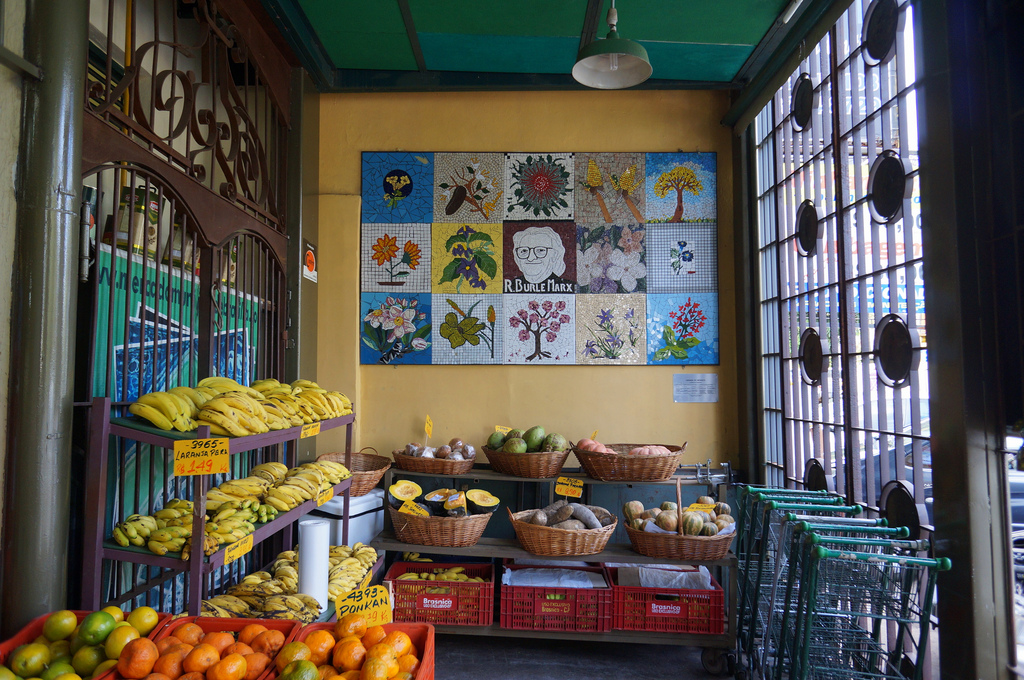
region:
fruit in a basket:
[620, 479, 732, 563]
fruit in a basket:
[514, 490, 623, 574]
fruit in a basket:
[389, 468, 503, 557]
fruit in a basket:
[471, 418, 585, 476]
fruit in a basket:
[394, 397, 483, 464]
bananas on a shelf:
[133, 375, 238, 440]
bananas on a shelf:
[264, 450, 329, 492]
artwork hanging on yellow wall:
[319, 89, 741, 466]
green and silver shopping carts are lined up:
[720, 480, 956, 677]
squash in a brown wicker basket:
[622, 473, 739, 563]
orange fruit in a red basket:
[266, 613, 440, 677]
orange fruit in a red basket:
[107, 610, 305, 677]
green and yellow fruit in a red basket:
[2, 600, 171, 677]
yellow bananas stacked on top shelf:
[113, 367, 367, 457]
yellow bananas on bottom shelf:
[177, 534, 390, 627]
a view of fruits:
[98, 574, 299, 673]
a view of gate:
[825, 195, 965, 467]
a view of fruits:
[128, 313, 341, 444]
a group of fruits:
[163, 395, 353, 652]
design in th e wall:
[496, 160, 601, 339]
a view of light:
[558, 42, 685, 123]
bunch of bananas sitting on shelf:
[137, 382, 198, 441]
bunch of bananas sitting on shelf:
[270, 484, 308, 519]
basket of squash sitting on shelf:
[388, 484, 496, 542]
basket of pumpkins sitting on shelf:
[576, 437, 688, 479]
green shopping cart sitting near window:
[794, 547, 951, 666]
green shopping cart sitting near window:
[744, 496, 863, 662]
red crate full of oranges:
[273, 606, 433, 671]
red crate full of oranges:
[126, 613, 292, 674]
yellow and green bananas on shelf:
[146, 373, 251, 440]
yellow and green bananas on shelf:
[263, 379, 330, 411]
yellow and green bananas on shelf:
[263, 461, 327, 493]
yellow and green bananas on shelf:
[193, 470, 295, 505]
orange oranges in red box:
[169, 625, 209, 648]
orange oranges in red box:
[257, 604, 303, 656]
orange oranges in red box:
[362, 636, 388, 671]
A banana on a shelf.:
[130, 403, 172, 427]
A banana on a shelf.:
[154, 381, 186, 416]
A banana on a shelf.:
[111, 520, 130, 540]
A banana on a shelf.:
[133, 517, 153, 537]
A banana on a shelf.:
[149, 535, 168, 552]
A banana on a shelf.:
[148, 528, 171, 538]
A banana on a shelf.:
[265, 485, 295, 502]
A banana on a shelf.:
[205, 375, 247, 394]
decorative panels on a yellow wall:
[308, 86, 727, 459]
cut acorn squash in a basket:
[385, 467, 499, 548]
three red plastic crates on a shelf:
[385, 549, 741, 649]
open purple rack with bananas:
[77, 374, 390, 625]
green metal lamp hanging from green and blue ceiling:
[303, 0, 790, 97]